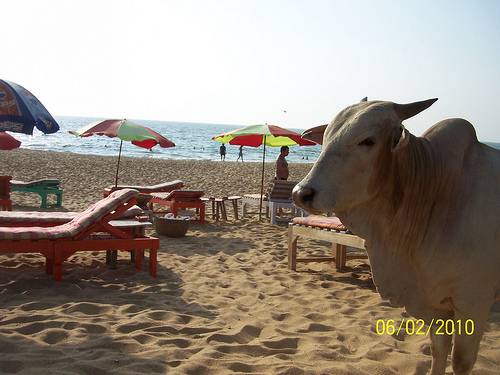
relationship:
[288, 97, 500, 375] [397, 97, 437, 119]
cow has horn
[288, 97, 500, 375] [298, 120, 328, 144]
cow has horn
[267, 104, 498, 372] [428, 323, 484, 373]
cow has legs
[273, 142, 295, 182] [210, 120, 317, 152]
man under umbrella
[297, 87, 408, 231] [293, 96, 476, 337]
head of cow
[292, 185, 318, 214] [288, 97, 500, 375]
nose of a cow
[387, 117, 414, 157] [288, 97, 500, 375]
ear on a cow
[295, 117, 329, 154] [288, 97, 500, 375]
ear on a cow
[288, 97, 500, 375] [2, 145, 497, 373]
cow on sand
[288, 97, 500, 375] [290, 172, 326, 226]
cow has nose